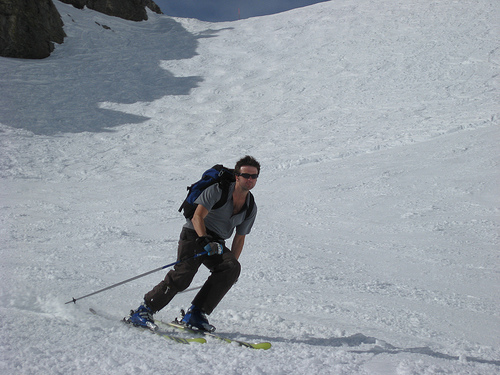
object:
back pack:
[181, 164, 234, 220]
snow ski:
[85, 305, 274, 355]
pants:
[143, 226, 241, 318]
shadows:
[7, 18, 209, 141]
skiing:
[63, 230, 278, 347]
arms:
[190, 185, 224, 258]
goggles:
[237, 172, 259, 179]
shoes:
[172, 305, 216, 332]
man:
[124, 153, 263, 336]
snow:
[0, 4, 496, 375]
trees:
[59, 1, 163, 18]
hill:
[134, 6, 499, 272]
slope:
[0, 1, 489, 373]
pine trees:
[0, 3, 66, 59]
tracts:
[4, 10, 493, 373]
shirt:
[183, 181, 259, 235]